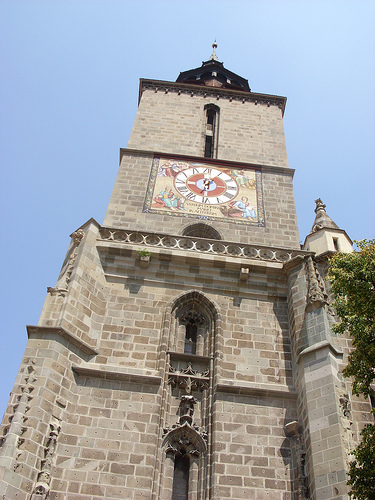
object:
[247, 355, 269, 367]
stone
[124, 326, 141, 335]
brick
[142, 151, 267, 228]
decorative square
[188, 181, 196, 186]
line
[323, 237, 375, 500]
tree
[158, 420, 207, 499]
arch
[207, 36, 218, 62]
spire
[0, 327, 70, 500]
brick work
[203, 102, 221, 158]
church wondow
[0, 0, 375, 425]
sky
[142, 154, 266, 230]
mural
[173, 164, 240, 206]
church clock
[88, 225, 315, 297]
ledge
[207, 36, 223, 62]
tip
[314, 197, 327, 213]
tip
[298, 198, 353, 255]
tower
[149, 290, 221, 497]
archway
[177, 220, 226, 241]
arch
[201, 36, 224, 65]
lightning rod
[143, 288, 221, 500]
designs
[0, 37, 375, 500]
church tower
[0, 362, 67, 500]
etching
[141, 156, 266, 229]
figures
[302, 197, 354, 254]
cupola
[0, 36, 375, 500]
clock tower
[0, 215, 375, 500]
bottom half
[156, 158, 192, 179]
people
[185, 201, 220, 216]
writing